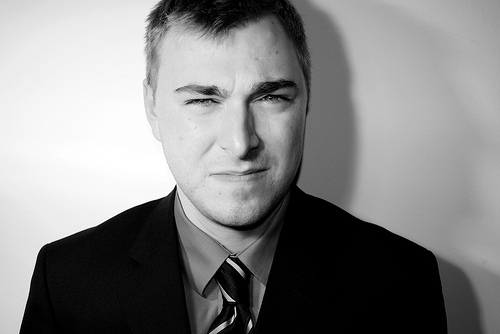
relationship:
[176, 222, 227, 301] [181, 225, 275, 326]
collar of shirt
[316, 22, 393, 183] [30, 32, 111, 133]
shadow across wall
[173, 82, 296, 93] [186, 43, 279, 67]
eyebrows across forehead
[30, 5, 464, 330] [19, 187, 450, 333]
man wearing jacket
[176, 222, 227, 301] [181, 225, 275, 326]
collar from shirt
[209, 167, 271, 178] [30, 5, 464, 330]
mouth of man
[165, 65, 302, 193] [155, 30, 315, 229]
concerned look across face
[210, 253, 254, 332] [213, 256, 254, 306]
tie has a knot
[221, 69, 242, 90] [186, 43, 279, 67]
line on forehead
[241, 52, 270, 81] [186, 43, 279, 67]
line on forehead